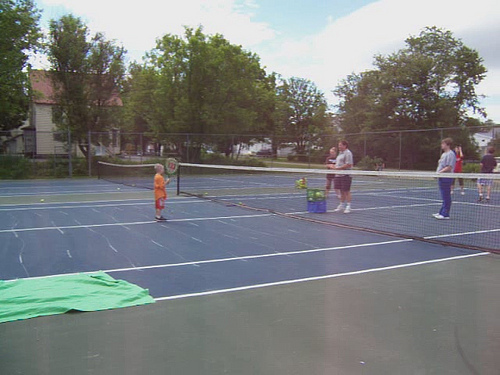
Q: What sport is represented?
A: Tennis.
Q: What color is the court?
A: Blue.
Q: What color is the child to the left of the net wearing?
A: Orange.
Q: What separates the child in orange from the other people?
A: Net.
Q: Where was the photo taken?
A: Tennis court.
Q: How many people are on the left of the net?
A: One.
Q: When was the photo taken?
A: Daytime.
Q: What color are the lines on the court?
A: White.